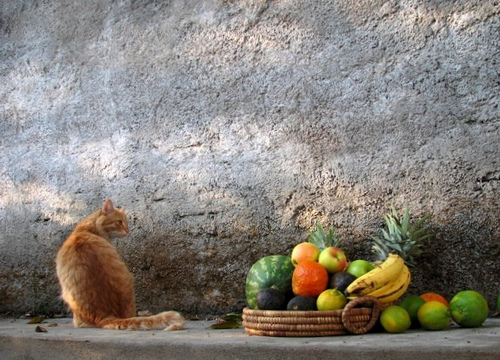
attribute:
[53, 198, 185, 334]
cat — yellow, sitting, striped, orange, white, shorthaired, orange striped, looking back, facing basket, looking at fruit, orange tanish color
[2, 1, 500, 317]
wall — cement, solid, gray, exterior, stone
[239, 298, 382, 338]
basket — woven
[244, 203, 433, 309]
fruit — piled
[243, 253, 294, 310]
watermellow — green, striped, big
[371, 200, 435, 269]
leaves — from pineapple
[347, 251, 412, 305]
bananas — yellow, turning black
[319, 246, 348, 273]
apple — red, green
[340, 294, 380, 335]
handle — circular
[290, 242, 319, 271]
apple — red, green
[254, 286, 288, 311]
avocado — green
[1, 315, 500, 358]
ledge — concrete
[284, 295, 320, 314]
avocado — green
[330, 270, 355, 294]
avocado — green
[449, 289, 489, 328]
lime — green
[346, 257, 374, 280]
apple — green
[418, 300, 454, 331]
lime — green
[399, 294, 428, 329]
lime — green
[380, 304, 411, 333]
lime — green